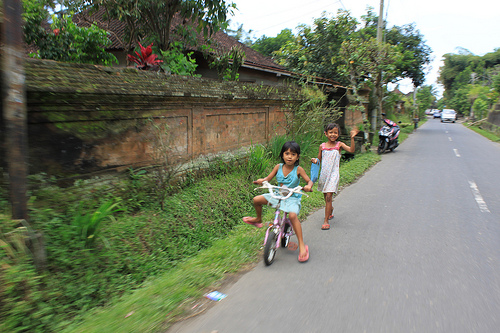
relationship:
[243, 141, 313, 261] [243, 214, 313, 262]
girls wearing flip flops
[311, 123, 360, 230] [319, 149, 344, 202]
girl wearing white sundress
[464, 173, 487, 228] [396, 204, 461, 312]
line on road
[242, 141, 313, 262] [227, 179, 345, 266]
girls on bike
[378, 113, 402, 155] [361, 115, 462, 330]
motorcycle parked on street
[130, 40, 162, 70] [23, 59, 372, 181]
red flower on wall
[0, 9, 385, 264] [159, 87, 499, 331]
wall along street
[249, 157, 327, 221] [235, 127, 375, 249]
outfit on girl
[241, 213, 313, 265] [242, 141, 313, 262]
flip flops on girls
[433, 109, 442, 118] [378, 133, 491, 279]
car on road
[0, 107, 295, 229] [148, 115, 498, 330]
wall by road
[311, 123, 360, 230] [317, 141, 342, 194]
girl wearing dress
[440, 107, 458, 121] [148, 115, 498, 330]
car on road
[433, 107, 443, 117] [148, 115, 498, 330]
car on road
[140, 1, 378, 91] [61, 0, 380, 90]
roof on building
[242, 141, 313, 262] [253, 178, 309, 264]
girls riding bicycle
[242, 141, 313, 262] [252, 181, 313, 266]
girls riding bike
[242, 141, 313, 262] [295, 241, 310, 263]
girls wearing sandal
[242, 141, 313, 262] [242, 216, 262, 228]
girls wearing flip flops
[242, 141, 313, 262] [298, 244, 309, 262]
girls wearing flip flops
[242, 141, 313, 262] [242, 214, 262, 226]
girls wearing sandal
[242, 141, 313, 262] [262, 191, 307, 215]
girls wearing skirt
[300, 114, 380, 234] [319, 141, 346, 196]
girl wearing dress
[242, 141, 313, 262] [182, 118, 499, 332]
girls at side of road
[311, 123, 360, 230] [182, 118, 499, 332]
girl at side of road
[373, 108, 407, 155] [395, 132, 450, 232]
motorcycle parked by road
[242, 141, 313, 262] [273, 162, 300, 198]
girls wearing top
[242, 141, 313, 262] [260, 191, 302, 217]
girls wearing skirt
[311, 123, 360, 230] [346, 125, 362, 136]
girl waving with hand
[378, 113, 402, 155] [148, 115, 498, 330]
motorcycle parked on side of road